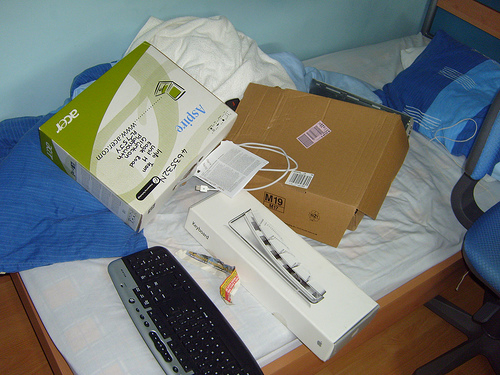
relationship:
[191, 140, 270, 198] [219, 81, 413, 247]
instructions on box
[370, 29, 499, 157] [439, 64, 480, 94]
pillow has stripes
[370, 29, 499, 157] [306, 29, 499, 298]
pillow on bed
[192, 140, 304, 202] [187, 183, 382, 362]
wire on box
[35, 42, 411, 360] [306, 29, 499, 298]
boxes on bed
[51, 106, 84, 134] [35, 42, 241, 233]
writing on boxes